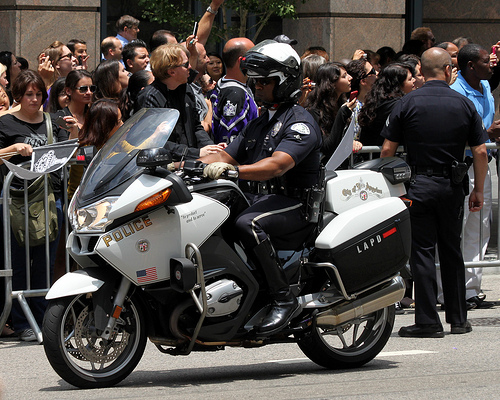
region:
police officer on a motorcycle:
[33, 19, 435, 399]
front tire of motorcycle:
[38, 255, 152, 393]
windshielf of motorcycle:
[58, 98, 189, 219]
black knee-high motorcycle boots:
[241, 226, 309, 368]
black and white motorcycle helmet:
[227, 31, 310, 118]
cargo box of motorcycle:
[308, 187, 421, 299]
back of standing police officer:
[375, 23, 495, 341]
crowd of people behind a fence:
[2, 26, 494, 166]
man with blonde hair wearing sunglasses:
[152, 38, 193, 122]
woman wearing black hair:
[8, 62, 57, 169]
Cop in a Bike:
[100, 57, 423, 354]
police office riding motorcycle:
[202, 31, 335, 343]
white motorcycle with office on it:
[42, 73, 456, 378]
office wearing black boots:
[171, 26, 310, 356]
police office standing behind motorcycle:
[376, 28, 477, 349]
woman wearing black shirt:
[2, 62, 67, 272]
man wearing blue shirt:
[452, 42, 491, 317]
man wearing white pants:
[451, 36, 491, 317]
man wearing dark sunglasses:
[140, 36, 207, 169]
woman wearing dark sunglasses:
[54, 66, 111, 171]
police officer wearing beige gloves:
[193, 25, 324, 342]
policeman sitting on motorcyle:
[41, 37, 427, 379]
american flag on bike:
[130, 257, 167, 294]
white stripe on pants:
[232, 200, 305, 248]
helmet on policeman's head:
[240, 37, 300, 107]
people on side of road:
[16, 43, 207, 190]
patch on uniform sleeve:
[281, 115, 313, 153]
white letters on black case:
[347, 232, 387, 261]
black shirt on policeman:
[398, 86, 477, 161]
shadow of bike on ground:
[192, 357, 317, 390]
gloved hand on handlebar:
[202, 158, 244, 186]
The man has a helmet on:
[231, 28, 316, 99]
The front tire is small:
[34, 260, 141, 395]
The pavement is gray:
[410, 321, 455, 391]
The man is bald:
[402, 39, 475, 91]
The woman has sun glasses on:
[67, 77, 104, 98]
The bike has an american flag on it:
[90, 233, 205, 338]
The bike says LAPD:
[333, 198, 433, 285]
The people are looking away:
[287, 20, 456, 161]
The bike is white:
[78, 117, 487, 287]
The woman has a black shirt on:
[26, 62, 86, 151]